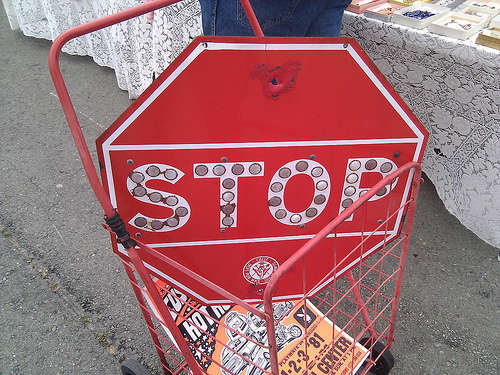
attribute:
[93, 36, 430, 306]
sign — red, stop sign, eight-sided, edged in white, orange, dirty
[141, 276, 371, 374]
poster — orange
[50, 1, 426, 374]
cart — red, metal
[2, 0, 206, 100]
tablecloth — lace, white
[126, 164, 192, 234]
letter — white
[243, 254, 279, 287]
logo — circular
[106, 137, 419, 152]
line — white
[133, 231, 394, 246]
line — white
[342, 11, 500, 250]
tablecloth — white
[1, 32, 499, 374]
ground — dirty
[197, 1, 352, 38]
jeans — blue